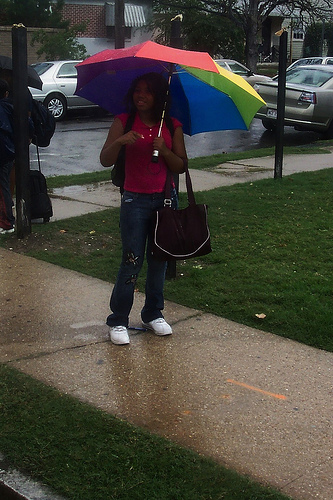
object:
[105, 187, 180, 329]
pants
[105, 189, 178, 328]
blue jeans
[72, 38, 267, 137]
umbrella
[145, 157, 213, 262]
purse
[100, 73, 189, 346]
girl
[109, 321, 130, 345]
shoes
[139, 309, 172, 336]
shoes